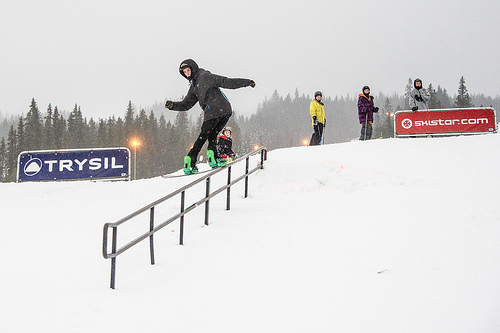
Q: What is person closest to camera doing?
A: Skiing.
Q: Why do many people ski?
A: For enjoyment.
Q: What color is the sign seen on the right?
A: Red.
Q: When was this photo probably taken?
A: Winter.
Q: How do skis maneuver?
A: By gliding.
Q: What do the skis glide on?
A: Snow.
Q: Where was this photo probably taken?
A: Ski slope.